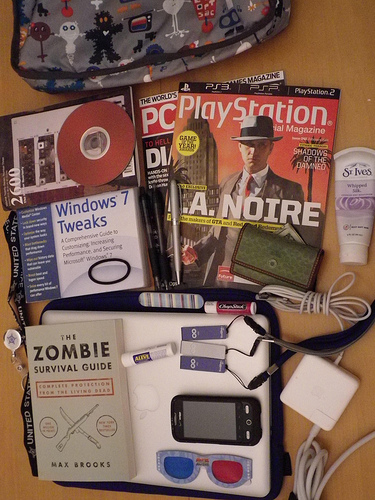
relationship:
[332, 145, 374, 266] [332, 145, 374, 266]
bottle of bottle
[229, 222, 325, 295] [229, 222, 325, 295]
billfold with billfold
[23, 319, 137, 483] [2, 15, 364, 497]
book on table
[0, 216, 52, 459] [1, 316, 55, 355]
lanyard with charm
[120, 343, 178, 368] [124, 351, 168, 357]
white tube of pain medicine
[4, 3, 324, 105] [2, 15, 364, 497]
bag on table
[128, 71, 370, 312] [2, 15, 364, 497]
magazines on table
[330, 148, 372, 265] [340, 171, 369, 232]
bottle of lotion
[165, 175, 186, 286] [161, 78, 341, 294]
ink pen on magazine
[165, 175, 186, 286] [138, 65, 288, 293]
ink pen on magazine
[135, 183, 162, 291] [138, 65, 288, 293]
ink pen on magazine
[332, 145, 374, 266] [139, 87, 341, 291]
bottle beside magazines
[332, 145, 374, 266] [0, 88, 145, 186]
bottle beside magazines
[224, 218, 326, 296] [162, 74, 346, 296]
billfold laying on magazines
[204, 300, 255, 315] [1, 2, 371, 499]
chapstick in foreground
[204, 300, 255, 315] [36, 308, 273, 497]
chapstick on pc